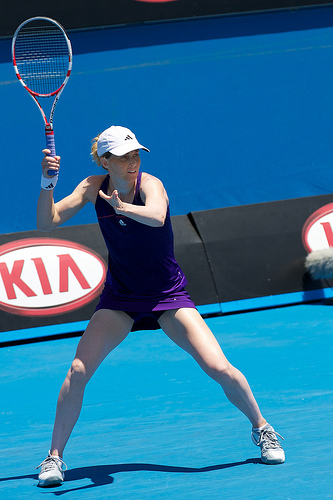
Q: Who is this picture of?
A: Female tennis player.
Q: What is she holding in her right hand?
A: Tennis racket.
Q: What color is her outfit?
A: Royal blue.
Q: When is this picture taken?
A: During a tennis match.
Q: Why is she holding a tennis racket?
A: She is playing tennis.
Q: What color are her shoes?
A: White.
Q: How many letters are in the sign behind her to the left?
A: Three.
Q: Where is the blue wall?
A: Directly behind the woman.